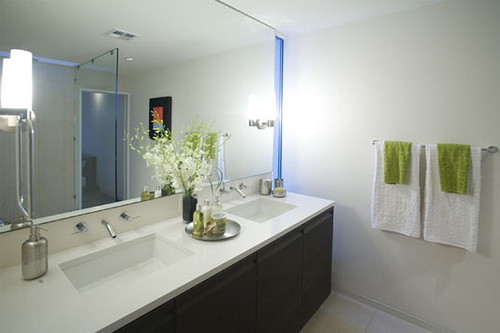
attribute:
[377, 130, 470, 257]
towels — white, some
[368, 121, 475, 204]
washcloths — green, olive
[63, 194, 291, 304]
sinks — in bathroom, rectangular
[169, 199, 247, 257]
tray — silver, circular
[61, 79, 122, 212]
door — reflected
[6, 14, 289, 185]
mirror — in bathroom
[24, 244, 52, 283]
soap dispenser — silver, metallic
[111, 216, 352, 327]
cabinets — brown, dark brown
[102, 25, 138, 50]
ceiling vent — in bathroom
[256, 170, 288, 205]
containers — metal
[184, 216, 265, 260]
plate — round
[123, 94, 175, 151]
frame — black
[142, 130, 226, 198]
bouquet — white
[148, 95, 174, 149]
artwork — black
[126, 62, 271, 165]
wall — white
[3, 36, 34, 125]
light — reflected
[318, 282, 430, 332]
floor — tiled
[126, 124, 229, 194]
flowers — white